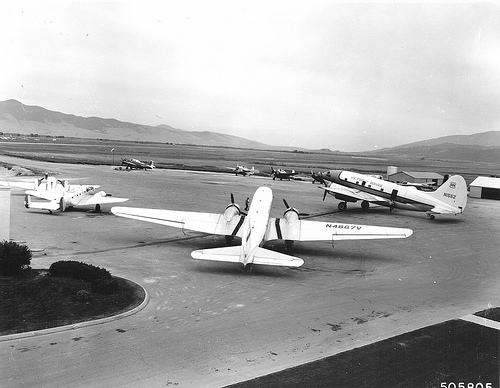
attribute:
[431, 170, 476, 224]
tail — airplane's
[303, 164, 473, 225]
plane — vintage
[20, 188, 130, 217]
plane —  vintage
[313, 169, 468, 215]
plane — vintage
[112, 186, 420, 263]
plane — vintage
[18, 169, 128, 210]
plane — vintage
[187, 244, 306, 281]
tail — flat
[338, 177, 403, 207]
stripe — along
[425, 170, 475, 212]
tail — curved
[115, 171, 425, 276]
airplanes — forming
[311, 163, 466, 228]
plane — vintage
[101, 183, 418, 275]
plane — vintage, white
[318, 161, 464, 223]
airplane — circular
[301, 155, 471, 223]
plane — small, painted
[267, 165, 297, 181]
plane — vintage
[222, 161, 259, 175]
plane — vintage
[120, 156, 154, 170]
plane — vintage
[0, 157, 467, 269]
planes — lined up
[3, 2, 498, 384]
outdoors — scene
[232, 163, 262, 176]
plane — vintage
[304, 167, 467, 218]
plane — sitting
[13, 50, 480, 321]
photo — black, white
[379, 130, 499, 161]
mountains — rounded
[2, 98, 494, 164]
mountain — in distance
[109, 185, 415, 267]
airplane — sitting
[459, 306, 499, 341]
line — white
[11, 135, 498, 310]
planes — packed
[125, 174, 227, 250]
wing — slanted, angled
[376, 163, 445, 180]
structure — flat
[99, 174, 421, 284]
plane — air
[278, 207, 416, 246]
wing — plane's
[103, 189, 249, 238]
wing — plane's